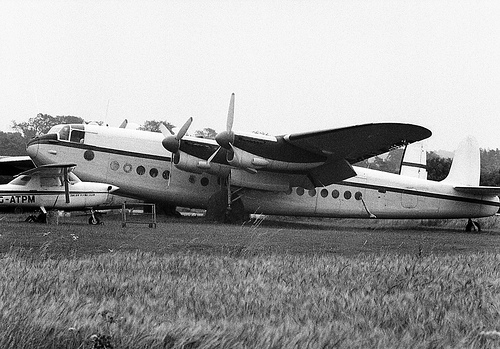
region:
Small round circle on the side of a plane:
[104, 156, 122, 174]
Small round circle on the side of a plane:
[119, 161, 131, 172]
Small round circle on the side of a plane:
[132, 161, 151, 184]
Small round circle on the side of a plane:
[161, 168, 170, 181]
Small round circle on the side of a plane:
[185, 170, 194, 184]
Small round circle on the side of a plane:
[303, 186, 318, 203]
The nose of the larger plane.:
[26, 137, 38, 155]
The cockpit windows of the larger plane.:
[52, 125, 83, 144]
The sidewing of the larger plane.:
[263, 119, 432, 173]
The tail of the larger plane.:
[443, 127, 485, 189]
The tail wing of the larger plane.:
[450, 185, 498, 198]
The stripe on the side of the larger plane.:
[29, 137, 496, 217]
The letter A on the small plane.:
[10, 193, 15, 204]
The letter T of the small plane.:
[16, 194, 21, 204]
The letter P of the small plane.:
[21, 194, 26, 204]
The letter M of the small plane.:
[27, 192, 35, 207]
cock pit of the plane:
[43, 117, 88, 154]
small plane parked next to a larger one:
[1, 105, 146, 240]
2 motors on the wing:
[146, 108, 308, 181]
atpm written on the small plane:
[6, 184, 44, 209]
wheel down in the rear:
[461, 219, 487, 239]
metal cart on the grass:
[110, 196, 165, 232]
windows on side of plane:
[99, 153, 171, 184]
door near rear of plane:
[401, 184, 434, 214]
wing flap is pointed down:
[301, 163, 378, 190]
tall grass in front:
[3, 235, 342, 345]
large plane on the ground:
[26, 120, 498, 232]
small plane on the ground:
[1, 160, 122, 222]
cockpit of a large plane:
[59, 120, 85, 145]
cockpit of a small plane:
[41, 170, 78, 192]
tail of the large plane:
[447, 138, 498, 210]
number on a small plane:
[1, 192, 36, 208]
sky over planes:
[1, 1, 498, 158]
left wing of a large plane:
[258, 115, 436, 180]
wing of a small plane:
[17, 163, 79, 174]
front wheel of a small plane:
[83, 204, 103, 229]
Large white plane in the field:
[24, 113, 494, 241]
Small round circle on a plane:
[103, 159, 120, 178]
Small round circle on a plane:
[122, 156, 131, 180]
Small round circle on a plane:
[133, 164, 147, 180]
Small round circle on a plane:
[146, 161, 161, 188]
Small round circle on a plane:
[155, 163, 176, 189]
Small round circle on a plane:
[183, 167, 200, 187]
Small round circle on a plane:
[198, 176, 208, 197]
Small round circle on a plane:
[353, 188, 366, 210]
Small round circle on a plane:
[340, 187, 353, 207]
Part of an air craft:
[33, 117, 133, 172]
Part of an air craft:
[87, 116, 173, 197]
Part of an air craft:
[216, 135, 314, 221]